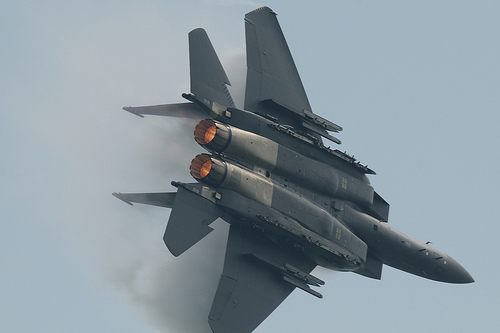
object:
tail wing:
[162, 186, 225, 257]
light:
[198, 160, 210, 176]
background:
[0, 23, 499, 132]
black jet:
[109, 7, 475, 333]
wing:
[207, 224, 316, 333]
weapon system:
[244, 253, 326, 298]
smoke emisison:
[148, 114, 217, 176]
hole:
[191, 154, 212, 179]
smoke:
[121, 249, 213, 333]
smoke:
[111, 47, 180, 101]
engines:
[188, 152, 227, 187]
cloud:
[122, 126, 193, 176]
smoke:
[115, 124, 189, 185]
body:
[363, 212, 478, 284]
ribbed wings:
[243, 6, 325, 147]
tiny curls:
[418, 248, 443, 260]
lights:
[204, 125, 216, 143]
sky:
[2, 0, 500, 333]